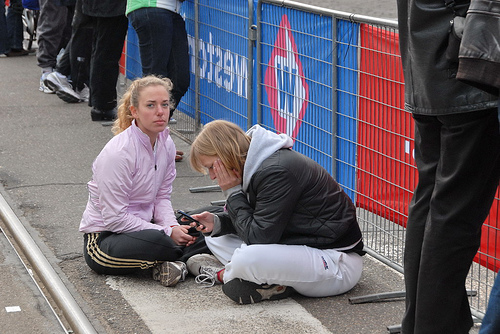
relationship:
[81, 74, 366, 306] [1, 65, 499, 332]
woman on sidewalk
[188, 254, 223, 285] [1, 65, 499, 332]
shoe on sidewalk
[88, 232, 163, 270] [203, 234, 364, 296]
stripes on pants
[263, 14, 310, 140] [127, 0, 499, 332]
logo behind fence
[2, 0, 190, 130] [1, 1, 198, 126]
legs on people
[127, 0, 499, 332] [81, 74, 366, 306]
fence behind woman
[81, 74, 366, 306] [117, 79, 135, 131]
woman with pony tail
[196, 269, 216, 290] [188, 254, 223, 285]
laces on shoe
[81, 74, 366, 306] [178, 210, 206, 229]
woman on phone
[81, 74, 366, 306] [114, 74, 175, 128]
woman with hair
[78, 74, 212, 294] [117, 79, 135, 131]
lady with pony tail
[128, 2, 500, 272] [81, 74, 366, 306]
banner behind woman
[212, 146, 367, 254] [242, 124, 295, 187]
jacket with hood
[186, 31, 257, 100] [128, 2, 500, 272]
word on banner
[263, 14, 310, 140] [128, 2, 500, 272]
logo on banner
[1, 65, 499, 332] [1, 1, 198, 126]
sidewalk under people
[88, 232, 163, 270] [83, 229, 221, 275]
stripes on pants